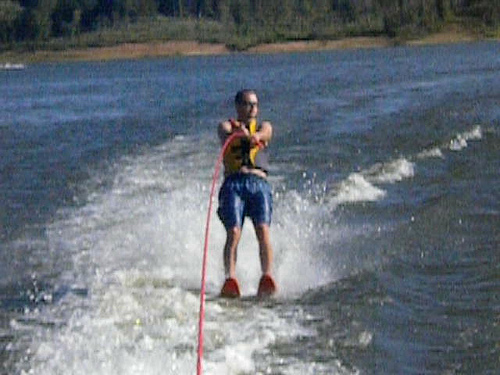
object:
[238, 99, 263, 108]
eyeglasses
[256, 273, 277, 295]
water ski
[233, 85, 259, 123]
head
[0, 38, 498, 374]
water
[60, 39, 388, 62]
dirt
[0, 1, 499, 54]
vegetation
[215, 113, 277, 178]
lifejacket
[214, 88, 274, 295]
man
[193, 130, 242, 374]
rope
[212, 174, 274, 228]
trunks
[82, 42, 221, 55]
sand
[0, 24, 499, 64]
beach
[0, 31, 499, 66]
shoreline